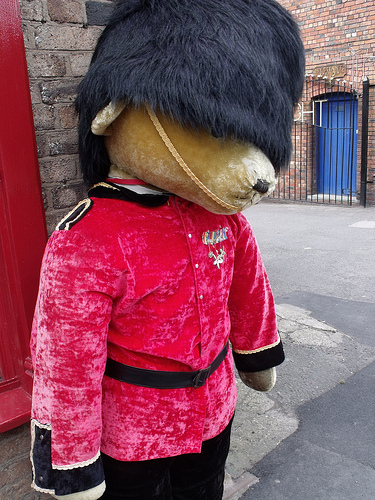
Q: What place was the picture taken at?
A: It was taken at the pavement.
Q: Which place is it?
A: It is a pavement.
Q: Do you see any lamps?
A: No, there are no lamps.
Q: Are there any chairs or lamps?
A: No, there are no lamps or chairs.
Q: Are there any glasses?
A: No, there are no glasses.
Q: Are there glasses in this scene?
A: No, there are no glasses.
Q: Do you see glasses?
A: No, there are no glasses.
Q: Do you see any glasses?
A: No, there are no glasses.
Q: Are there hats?
A: Yes, there is a hat.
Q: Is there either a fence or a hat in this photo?
A: Yes, there is a hat.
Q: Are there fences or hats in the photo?
A: Yes, there is a hat.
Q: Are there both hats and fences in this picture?
A: Yes, there are both a hat and a fence.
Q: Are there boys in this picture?
A: No, there are no boys.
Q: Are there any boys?
A: No, there are no boys.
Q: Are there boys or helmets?
A: No, there are no boys or helmets.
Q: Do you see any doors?
A: Yes, there is a door.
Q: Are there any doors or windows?
A: Yes, there is a door.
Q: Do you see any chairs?
A: No, there are no chairs.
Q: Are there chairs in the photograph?
A: No, there are no chairs.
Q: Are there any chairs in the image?
A: No, there are no chairs.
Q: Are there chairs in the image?
A: No, there are no chairs.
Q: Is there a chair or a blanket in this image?
A: No, there are no chairs or blankets.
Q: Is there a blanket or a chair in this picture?
A: No, there are no chairs or blankets.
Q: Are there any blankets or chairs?
A: No, there are no chairs or blankets.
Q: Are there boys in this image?
A: No, there are no boys.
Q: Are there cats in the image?
A: No, there are no cats.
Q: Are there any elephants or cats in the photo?
A: No, there are no cats or elephants.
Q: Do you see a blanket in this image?
A: No, there are no blankets.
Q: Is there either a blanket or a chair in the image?
A: No, there are no blankets or chairs.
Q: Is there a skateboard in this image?
A: No, there are no skateboards.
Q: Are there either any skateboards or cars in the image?
A: No, there are no skateboards or cars.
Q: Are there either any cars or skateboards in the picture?
A: No, there are no skateboards or cars.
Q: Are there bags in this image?
A: No, there are no bags.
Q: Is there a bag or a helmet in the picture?
A: No, there are no bags or helmets.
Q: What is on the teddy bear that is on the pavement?
A: The jacket is on the teddy bear.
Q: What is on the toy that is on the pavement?
A: The jacket is on the teddy bear.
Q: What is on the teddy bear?
A: The jacket is on the teddy bear.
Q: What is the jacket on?
A: The jacket is on the teddy bear.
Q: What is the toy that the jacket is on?
A: The toy is a teddy bear.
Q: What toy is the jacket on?
A: The jacket is on the teddy bear.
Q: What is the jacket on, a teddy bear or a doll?
A: The jacket is on a teddy bear.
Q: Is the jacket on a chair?
A: No, the jacket is on a teddy bear.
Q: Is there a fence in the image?
A: Yes, there is a fence.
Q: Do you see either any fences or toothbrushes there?
A: Yes, there is a fence.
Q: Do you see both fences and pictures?
A: No, there is a fence but no pictures.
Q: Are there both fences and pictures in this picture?
A: No, there is a fence but no pictures.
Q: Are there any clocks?
A: No, there are no clocks.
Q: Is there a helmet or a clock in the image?
A: No, there are no clocks or helmets.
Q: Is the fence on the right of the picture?
A: Yes, the fence is on the right of the image.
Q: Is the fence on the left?
A: No, the fence is on the right of the image.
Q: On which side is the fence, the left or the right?
A: The fence is on the right of the image.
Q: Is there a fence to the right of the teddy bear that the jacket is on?
A: Yes, there is a fence to the right of the teddy bear.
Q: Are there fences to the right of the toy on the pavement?
A: Yes, there is a fence to the right of the teddy bear.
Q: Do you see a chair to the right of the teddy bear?
A: No, there is a fence to the right of the teddy bear.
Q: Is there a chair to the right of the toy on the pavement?
A: No, there is a fence to the right of the teddy bear.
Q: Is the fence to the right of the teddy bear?
A: Yes, the fence is to the right of the teddy bear.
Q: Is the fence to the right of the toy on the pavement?
A: Yes, the fence is to the right of the teddy bear.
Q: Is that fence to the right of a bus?
A: No, the fence is to the right of the teddy bear.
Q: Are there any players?
A: No, there are no players.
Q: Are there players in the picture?
A: No, there are no players.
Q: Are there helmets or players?
A: No, there are no players or helmets.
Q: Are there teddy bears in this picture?
A: Yes, there is a teddy bear.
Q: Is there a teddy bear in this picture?
A: Yes, there is a teddy bear.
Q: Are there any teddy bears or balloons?
A: Yes, there is a teddy bear.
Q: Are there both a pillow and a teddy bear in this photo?
A: No, there is a teddy bear but no pillows.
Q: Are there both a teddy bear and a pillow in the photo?
A: No, there is a teddy bear but no pillows.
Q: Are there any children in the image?
A: No, there are no children.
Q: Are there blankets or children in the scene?
A: No, there are no children or blankets.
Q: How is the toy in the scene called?
A: The toy is a teddy bear.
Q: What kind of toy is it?
A: The toy is a teddy bear.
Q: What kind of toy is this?
A: This is a teddy bear.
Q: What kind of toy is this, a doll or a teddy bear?
A: This is a teddy bear.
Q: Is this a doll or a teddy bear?
A: This is a teddy bear.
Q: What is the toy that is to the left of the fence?
A: The toy is a teddy bear.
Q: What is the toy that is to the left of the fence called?
A: The toy is a teddy bear.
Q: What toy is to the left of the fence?
A: The toy is a teddy bear.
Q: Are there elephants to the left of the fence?
A: No, there is a teddy bear to the left of the fence.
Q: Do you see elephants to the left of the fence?
A: No, there is a teddy bear to the left of the fence.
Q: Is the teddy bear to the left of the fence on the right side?
A: Yes, the teddy bear is to the left of the fence.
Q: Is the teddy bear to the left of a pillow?
A: No, the teddy bear is to the left of the fence.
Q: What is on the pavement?
A: The teddy bear is on the pavement.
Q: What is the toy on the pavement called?
A: The toy is a teddy bear.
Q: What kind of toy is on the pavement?
A: The toy is a teddy bear.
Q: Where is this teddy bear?
A: The teddy bear is on the pavement.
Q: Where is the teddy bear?
A: The teddy bear is on the pavement.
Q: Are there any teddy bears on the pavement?
A: Yes, there is a teddy bear on the pavement.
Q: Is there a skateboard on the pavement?
A: No, there is a teddy bear on the pavement.